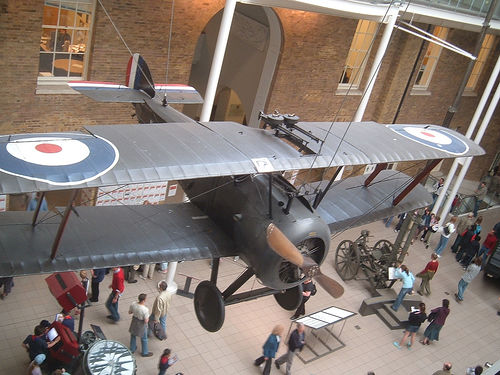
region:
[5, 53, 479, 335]
model airplane suspended from ceiling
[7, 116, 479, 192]
red, white, and blue circles on plane's wing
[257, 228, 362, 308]
two blade propellor of plane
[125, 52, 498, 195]
wires attaching plane to ceiling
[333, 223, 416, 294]
cannon on floor of museum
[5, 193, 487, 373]
people touring the museum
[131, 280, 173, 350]
two people wearing tan shirts standing together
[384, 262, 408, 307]
woman looking at cannon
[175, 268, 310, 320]
front black wheels of plane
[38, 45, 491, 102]
windows on brown wall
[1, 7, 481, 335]
a plane hung by wires in a museum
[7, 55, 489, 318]
a plane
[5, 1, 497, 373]
a museum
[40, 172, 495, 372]
people looking at displays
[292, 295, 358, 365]
a sign on the floor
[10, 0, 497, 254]
a brick wall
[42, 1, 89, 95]
an office area is seen through the window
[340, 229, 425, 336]
a metal obstacle on display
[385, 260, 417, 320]
a woman stands on a podium to read a display sign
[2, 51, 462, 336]
the plane is a propeller style aircraft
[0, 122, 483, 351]
a airplane hanging from ceiling in a mussem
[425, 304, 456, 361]
a woman wearing a skirt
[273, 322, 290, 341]
a woman with blonde hair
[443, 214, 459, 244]
a woman wearing a white shirt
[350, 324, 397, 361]
a tile floor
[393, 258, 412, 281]
a woman with brown hair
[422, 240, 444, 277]
a person wearing a red shirt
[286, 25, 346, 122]
a red brick wall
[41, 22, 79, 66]
a person sitting at a desk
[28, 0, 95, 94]
a window with white trim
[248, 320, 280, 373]
Person with black pants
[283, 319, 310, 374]
Person wearing kakki pants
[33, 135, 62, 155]
REd dot with white background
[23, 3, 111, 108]
Wondow of a brick building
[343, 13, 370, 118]
Wondow of a brick building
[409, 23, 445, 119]
Wondow of a brick building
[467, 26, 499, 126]
Wondow of a brick building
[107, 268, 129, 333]
Person walking on pavement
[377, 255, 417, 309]
Person walking on pavement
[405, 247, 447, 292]
Person walking on pavement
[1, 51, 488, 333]
the airplane is hanging from the ceiling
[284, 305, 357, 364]
the solar panels are on the floor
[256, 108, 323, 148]
the airplane has two guns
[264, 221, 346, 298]
the airplane has a propellar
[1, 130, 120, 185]
their is a target on the airplane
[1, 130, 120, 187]
the target is red, white and blue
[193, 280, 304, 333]
there are two wheels on the airplane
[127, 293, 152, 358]
his jacket is around his waist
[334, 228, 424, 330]
the girl is looking at the cannon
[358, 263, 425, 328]
she is standing on a platform